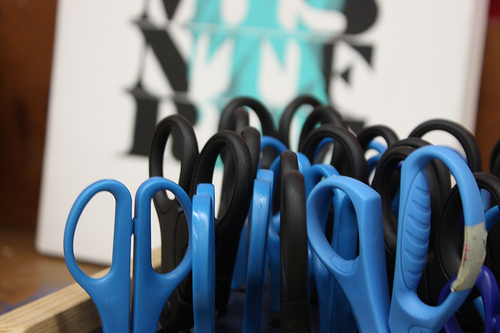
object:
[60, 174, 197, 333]
collection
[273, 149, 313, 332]
scissors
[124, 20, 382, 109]
word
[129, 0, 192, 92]
n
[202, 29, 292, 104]
t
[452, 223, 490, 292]
handle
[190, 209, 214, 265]
part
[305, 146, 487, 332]
scissors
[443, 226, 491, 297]
tape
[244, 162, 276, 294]
handle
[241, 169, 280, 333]
scissors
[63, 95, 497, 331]
group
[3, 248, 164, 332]
container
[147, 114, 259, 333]
scissors.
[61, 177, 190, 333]
scissors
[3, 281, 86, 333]
wood